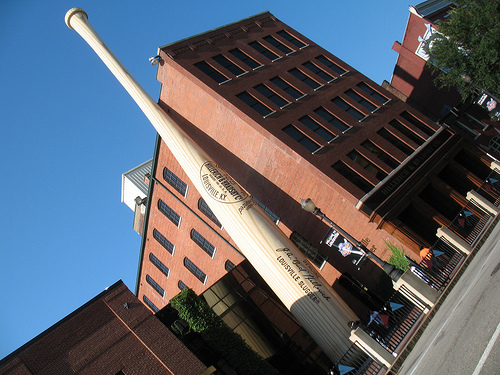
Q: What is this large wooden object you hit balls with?
A: Baseball bat.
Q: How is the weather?
A: Sunny.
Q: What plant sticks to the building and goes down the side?
A: Ivy.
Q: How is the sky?
A: Clear.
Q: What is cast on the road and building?
A: Shadow.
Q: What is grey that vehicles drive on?
A: Road.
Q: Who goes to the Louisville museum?
A: People who like baseball.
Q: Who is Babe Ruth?
A: Famous baseball player.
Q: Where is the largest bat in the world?
A: In front of the building.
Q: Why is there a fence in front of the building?
A: To keep cars out.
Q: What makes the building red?
A: Red bricks.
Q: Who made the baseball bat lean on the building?
A: To make it look real.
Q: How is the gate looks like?
A: Metal.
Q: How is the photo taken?
A: Side angle.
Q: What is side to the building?
A: Baseball bat.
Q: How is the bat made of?
A: Wood.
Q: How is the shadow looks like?
A: Casting.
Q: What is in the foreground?
A: Fence.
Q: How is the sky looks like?
A: Clear.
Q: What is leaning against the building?
A: A giant baseball bat.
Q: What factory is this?
A: Louisville Slugger.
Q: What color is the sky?
A: Blue.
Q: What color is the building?
A: Brown.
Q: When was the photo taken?
A: Daytime.